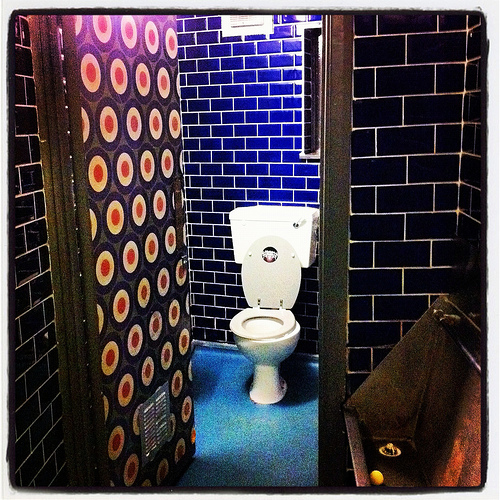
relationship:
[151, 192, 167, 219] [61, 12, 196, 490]
circle design on door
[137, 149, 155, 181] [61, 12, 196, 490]
circle design on door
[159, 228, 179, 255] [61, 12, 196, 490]
circle design on door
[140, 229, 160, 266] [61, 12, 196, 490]
circle design on door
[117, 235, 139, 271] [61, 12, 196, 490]
circle design on door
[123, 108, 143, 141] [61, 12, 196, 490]
circle design on door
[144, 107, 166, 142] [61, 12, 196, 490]
circle design on door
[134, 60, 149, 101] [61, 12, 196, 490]
circle design on door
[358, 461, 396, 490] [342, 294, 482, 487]
ball in metal tub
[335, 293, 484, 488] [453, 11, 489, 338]
metal tub attached to wall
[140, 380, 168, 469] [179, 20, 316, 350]
vent in side of wall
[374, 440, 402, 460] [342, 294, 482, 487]
drain system in metal tub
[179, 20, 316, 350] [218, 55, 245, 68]
wall has brick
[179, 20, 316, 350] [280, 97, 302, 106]
wall has brick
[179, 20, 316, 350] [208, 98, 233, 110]
wall has brick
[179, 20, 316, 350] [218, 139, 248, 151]
wall has brick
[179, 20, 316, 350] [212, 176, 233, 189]
wall has tile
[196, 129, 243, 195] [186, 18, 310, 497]
tile on wall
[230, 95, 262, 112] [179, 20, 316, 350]
tile on wall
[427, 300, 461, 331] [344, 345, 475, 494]
faucet into tub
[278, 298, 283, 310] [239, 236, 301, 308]
hinges on toilet seat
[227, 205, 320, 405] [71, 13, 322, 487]
toilet in bathroom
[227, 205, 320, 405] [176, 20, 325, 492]
toilet in restroom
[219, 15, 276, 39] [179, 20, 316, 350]
white on wall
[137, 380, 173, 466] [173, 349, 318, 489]
vent on floor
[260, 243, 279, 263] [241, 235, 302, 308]
sticker on lid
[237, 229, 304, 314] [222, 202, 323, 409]
lid on toilet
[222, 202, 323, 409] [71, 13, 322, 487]
toilet in bathroom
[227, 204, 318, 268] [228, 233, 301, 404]
tank on toilet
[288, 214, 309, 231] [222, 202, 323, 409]
flusher on toilet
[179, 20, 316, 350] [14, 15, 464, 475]
wall in bathroom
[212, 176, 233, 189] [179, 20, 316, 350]
tile on wall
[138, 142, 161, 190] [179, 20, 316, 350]
bullseye on wall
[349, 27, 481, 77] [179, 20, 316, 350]
tiles on wall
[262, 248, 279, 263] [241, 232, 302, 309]
sticker on lid